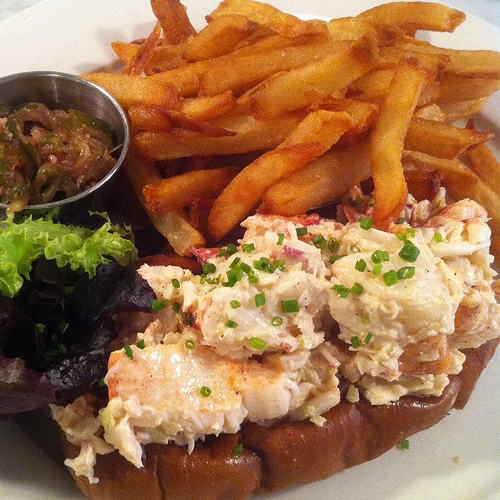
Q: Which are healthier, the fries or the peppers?
A: The peppers are healthier than the fries.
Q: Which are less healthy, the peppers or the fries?
A: The fries are less healthy than the peppers.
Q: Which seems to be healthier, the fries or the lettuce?
A: The lettuce is healthier than the fries.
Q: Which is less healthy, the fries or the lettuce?
A: The fries is less healthy than the lettuce.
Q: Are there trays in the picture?
A: No, there are no trays.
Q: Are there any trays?
A: No, there are no trays.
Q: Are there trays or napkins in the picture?
A: No, there are no trays or napkins.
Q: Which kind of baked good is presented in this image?
A: The baked good is a bun.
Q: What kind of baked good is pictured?
A: The baked good is a bun.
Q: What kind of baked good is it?
A: The food is a bun.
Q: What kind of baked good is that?
A: That is a bun.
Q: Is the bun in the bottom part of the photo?
A: Yes, the bun is in the bottom of the image.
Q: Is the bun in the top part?
A: No, the bun is in the bottom of the image.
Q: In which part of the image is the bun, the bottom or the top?
A: The bun is in the bottom of the image.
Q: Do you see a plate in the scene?
A: Yes, there is a plate.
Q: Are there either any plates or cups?
A: Yes, there is a plate.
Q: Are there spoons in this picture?
A: No, there are no spoons.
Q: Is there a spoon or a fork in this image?
A: No, there are no spoons or forks.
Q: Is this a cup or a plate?
A: This is a plate.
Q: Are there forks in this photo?
A: No, there are no forks.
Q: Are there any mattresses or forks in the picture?
A: No, there are no forks or mattresses.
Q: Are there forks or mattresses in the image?
A: No, there are no forks or mattresses.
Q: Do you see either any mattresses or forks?
A: No, there are no forks or mattresses.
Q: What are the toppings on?
A: The toppings are on the bun.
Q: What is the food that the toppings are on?
A: The food is a bun.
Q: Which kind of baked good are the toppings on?
A: The toppings are on the bun.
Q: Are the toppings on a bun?
A: Yes, the toppings are on a bun.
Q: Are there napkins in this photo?
A: No, there are no napkins.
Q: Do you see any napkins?
A: No, there are no napkins.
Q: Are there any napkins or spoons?
A: No, there are no napkins or spoons.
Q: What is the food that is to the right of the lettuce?
A: The food is tuna.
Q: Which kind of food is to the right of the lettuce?
A: The food is tuna.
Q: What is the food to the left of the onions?
A: The food is tuna.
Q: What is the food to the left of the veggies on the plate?
A: The food is tuna.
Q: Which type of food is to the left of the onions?
A: The food is tuna.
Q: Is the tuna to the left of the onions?
A: Yes, the tuna is to the left of the onions.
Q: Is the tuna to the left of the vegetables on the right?
A: Yes, the tuna is to the left of the onions.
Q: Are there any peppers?
A: Yes, there are peppers.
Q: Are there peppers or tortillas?
A: Yes, there are peppers.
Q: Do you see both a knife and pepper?
A: No, there are peppers but no knives.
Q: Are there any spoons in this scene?
A: No, there are no spoons.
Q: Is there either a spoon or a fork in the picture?
A: No, there are no spoons or forks.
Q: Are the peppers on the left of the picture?
A: Yes, the peppers are on the left of the image.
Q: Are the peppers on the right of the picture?
A: No, the peppers are on the left of the image.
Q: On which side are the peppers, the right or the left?
A: The peppers are on the left of the image.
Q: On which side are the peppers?
A: The peppers are on the left of the image.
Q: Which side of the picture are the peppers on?
A: The peppers are on the left of the image.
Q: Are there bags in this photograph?
A: No, there are no bags.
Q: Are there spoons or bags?
A: No, there are no bags or spoons.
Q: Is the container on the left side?
A: Yes, the container is on the left of the image.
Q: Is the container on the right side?
A: No, the container is on the left of the image.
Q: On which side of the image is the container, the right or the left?
A: The container is on the left of the image.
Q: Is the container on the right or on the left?
A: The container is on the left of the image.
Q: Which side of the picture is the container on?
A: The container is on the left of the image.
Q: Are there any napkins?
A: No, there are no napkins.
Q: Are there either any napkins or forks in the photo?
A: No, there are no napkins or forks.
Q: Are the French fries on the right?
A: Yes, the French fries are on the right of the image.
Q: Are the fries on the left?
A: No, the fries are on the right of the image.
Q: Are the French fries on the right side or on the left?
A: The French fries are on the right of the image.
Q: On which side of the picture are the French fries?
A: The French fries are on the right of the image.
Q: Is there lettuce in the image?
A: Yes, there is lettuce.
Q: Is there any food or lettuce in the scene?
A: Yes, there is lettuce.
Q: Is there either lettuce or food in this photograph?
A: Yes, there is lettuce.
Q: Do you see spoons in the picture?
A: No, there are no spoons.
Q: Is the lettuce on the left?
A: Yes, the lettuce is on the left of the image.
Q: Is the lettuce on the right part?
A: No, the lettuce is on the left of the image.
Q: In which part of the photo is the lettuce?
A: The lettuce is on the left of the image.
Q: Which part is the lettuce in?
A: The lettuce is on the left of the image.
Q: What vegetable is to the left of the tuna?
A: The vegetable is lettuce.